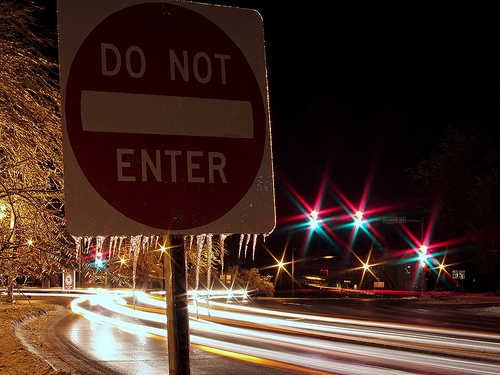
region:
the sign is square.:
[50, 7, 325, 282]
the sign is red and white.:
[62, 14, 308, 296]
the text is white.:
[65, 19, 265, 231]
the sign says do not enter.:
[46, 17, 276, 242]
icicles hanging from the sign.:
[60, 190, 280, 285]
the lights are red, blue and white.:
[300, 157, 385, 252]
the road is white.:
[70, 251, 486, 372]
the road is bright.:
[70, 262, 475, 364]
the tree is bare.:
[1, 71, 166, 256]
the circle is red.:
[62, 26, 294, 243]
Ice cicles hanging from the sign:
[67, 215, 278, 267]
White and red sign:
[58, 3, 300, 250]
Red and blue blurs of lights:
[273, 162, 485, 302]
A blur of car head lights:
[49, 277, 251, 362]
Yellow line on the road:
[97, 289, 268, 373]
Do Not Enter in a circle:
[64, 5, 268, 246]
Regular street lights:
[259, 251, 323, 310]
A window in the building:
[442, 262, 471, 288]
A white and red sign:
[46, 247, 88, 299]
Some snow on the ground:
[408, 295, 498, 317]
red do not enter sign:
[36, 0, 288, 293]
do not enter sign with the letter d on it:
[40, 36, 270, 226]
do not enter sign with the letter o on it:
[40, 30, 295, 236]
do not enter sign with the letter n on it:
[38, 22, 279, 278]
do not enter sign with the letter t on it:
[55, 35, 312, 240]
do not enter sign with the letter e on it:
[37, 25, 277, 253]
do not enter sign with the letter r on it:
[20, 42, 291, 289]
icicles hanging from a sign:
[20, 10, 276, 276]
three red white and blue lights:
[272, 160, 477, 301]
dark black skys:
[276, 36, 470, 175]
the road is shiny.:
[77, 267, 486, 372]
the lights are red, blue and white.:
[280, 163, 476, 285]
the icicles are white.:
[55, 216, 278, 299]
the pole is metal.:
[150, 236, 210, 373]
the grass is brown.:
[3, 271, 77, 373]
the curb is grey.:
[35, 296, 200, 373]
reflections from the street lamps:
[286, 198, 475, 304]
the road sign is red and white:
[76, 9, 276, 232]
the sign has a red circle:
[71, 27, 271, 205]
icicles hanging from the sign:
[63, 211, 308, 309]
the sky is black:
[296, 24, 483, 164]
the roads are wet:
[62, 298, 156, 371]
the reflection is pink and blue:
[289, 178, 474, 280]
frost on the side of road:
[14, 302, 49, 372]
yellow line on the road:
[215, 337, 310, 372]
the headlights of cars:
[185, 270, 283, 310]